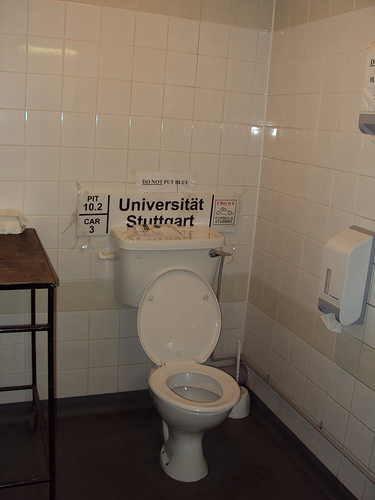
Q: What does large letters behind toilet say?
A: Universitat stuttgart.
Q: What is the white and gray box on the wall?
A: Toilet paper dispenser.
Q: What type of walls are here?
A: White tile.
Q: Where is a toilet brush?
A: On floor.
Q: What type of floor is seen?
A: Gray vinyl.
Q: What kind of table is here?
A: Brown wood with wheels.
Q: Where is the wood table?
A: Left side of toilet.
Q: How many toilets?
A: One.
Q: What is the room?
A: A bathroom.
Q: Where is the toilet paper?
A: In the dispenser.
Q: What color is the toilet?
A: White.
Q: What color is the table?
A: Brown.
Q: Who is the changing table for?
A: A baby.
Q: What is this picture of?
A: A restroom.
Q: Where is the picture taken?
A: In bathroom.